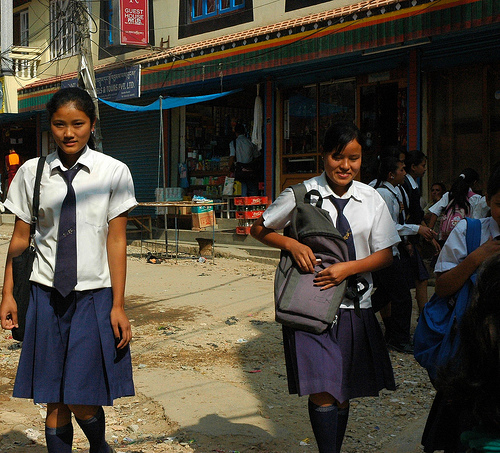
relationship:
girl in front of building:
[247, 122, 402, 453] [168, 58, 326, 139]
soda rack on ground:
[237, 204, 271, 223] [1, 212, 498, 452]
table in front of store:
[134, 187, 233, 259] [4, 9, 496, 211]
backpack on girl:
[273, 180, 352, 332] [247, 122, 402, 453]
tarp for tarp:
[92, 87, 235, 116] [97, 89, 235, 112]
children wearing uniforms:
[0, 74, 498, 451] [0, 144, 407, 420]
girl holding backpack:
[241, 114, 410, 414] [264, 180, 355, 333]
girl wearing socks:
[247, 122, 402, 453] [273, 385, 416, 450]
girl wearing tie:
[247, 122, 402, 453] [328, 195, 363, 308]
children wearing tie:
[0, 86, 137, 452] [53, 165, 80, 297]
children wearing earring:
[0, 86, 137, 452] [88, 124, 95, 141]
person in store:
[228, 123, 257, 198] [139, 0, 499, 230]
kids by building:
[378, 127, 479, 247] [53, 35, 480, 216]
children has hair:
[0, 86, 137, 452] [47, 87, 94, 125]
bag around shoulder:
[18, 148, 40, 345] [5, 142, 64, 236]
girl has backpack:
[247, 122, 402, 453] [273, 180, 351, 335]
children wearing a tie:
[0, 86, 137, 452] [52, 165, 82, 295]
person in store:
[226, 126, 249, 196] [170, 80, 269, 227]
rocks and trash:
[354, 335, 431, 449] [341, 333, 438, 449]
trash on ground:
[341, 333, 438, 449] [2, 217, 444, 451]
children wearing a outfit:
[0, 86, 137, 452] [1, 145, 141, 407]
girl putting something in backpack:
[247, 122, 402, 453] [273, 180, 352, 332]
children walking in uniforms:
[0, 86, 137, 452] [9, 149, 401, 398]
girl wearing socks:
[247, 122, 402, 453] [308, 402, 356, 450]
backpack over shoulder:
[273, 180, 351, 335] [285, 177, 314, 204]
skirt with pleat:
[10, 290, 137, 405] [59, 316, 77, 399]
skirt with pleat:
[10, 290, 137, 405] [28, 304, 40, 398]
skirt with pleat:
[10, 290, 137, 405] [95, 300, 112, 401]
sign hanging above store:
[103, 55, 181, 139] [169, 50, 337, 236]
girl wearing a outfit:
[247, 122, 402, 453] [260, 184, 394, 399]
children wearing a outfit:
[0, 86, 137, 452] [6, 149, 132, 399]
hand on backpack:
[311, 261, 347, 290] [273, 180, 352, 332]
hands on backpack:
[292, 243, 317, 274] [273, 180, 352, 332]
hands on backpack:
[278, 237, 345, 292] [273, 180, 352, 332]